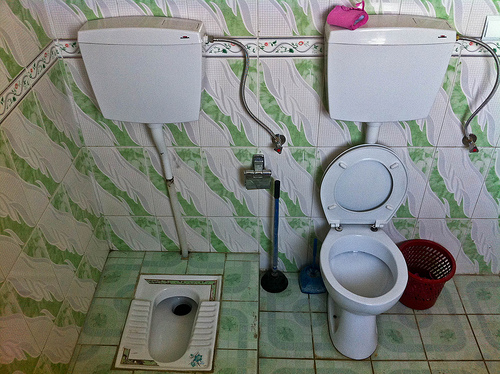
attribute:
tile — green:
[108, 250, 497, 371]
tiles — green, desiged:
[261, 311, 313, 359]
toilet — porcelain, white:
[317, 136, 410, 362]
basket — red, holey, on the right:
[393, 234, 456, 310]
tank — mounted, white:
[327, 15, 456, 125]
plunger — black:
[259, 175, 291, 293]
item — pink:
[324, 3, 368, 34]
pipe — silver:
[206, 29, 286, 153]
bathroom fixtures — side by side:
[81, 18, 450, 122]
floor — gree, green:
[260, 267, 499, 373]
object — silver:
[245, 151, 273, 189]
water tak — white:
[79, 19, 205, 124]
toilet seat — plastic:
[320, 146, 406, 233]